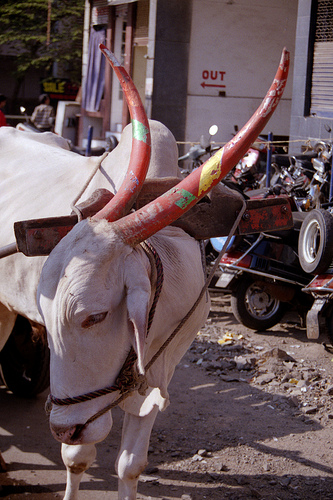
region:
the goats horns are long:
[39, 30, 322, 284]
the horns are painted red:
[43, 35, 287, 242]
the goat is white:
[3, 92, 262, 482]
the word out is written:
[176, 46, 237, 92]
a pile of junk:
[220, 115, 323, 320]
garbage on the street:
[196, 325, 313, 477]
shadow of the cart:
[155, 369, 314, 487]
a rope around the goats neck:
[132, 224, 184, 330]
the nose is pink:
[36, 402, 111, 447]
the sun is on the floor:
[218, 423, 325, 489]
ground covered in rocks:
[221, 439, 332, 498]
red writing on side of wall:
[189, 62, 240, 100]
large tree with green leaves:
[0, 0, 77, 75]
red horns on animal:
[92, 37, 296, 249]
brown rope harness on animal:
[31, 349, 159, 460]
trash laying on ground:
[206, 333, 310, 407]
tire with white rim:
[293, 209, 332, 281]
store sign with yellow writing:
[37, 73, 72, 94]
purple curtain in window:
[81, 22, 105, 113]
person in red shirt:
[0, 92, 15, 130]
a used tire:
[297, 210, 332, 270]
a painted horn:
[90, 38, 153, 225]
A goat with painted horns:
[17, 28, 295, 498]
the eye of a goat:
[75, 302, 113, 336]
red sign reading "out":
[192, 64, 235, 95]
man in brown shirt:
[30, 93, 56, 130]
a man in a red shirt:
[0, 95, 13, 127]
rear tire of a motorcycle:
[230, 271, 292, 330]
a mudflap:
[301, 293, 330, 341]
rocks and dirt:
[180, 356, 331, 498]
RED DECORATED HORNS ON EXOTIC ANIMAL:
[120, 72, 242, 245]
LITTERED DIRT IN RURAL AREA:
[200, 327, 332, 412]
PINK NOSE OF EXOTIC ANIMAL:
[47, 412, 92, 437]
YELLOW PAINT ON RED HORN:
[199, 148, 229, 189]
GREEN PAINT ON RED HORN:
[134, 121, 155, 142]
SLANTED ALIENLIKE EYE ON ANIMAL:
[75, 305, 107, 323]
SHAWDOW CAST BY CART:
[175, 352, 275, 447]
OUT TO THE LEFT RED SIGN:
[187, 60, 235, 91]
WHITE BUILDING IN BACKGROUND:
[83, 3, 329, 142]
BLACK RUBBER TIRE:
[297, 208, 332, 269]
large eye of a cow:
[78, 296, 122, 335]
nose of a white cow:
[38, 399, 118, 451]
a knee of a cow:
[109, 441, 150, 484]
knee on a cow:
[54, 435, 105, 474]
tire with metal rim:
[224, 271, 299, 333]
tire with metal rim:
[293, 201, 331, 276]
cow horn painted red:
[107, 35, 313, 260]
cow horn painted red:
[86, 40, 151, 228]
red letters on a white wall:
[188, 62, 246, 101]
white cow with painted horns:
[3, 31, 300, 499]